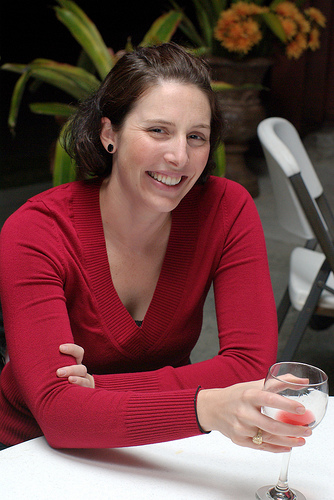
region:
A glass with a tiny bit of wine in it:
[260, 358, 328, 498]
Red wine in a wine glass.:
[277, 405, 315, 427]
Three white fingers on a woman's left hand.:
[49, 341, 94, 388]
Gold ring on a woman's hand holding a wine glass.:
[249, 424, 264, 443]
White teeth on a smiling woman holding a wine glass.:
[147, 170, 182, 186]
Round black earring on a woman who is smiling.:
[106, 142, 115, 152]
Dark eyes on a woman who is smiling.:
[147, 126, 202, 139]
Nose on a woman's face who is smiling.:
[163, 128, 190, 168]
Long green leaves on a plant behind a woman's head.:
[5, 0, 231, 181]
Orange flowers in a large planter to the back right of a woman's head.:
[212, 0, 326, 62]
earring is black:
[101, 142, 121, 153]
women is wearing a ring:
[250, 428, 267, 444]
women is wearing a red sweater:
[3, 227, 107, 341]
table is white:
[83, 460, 172, 496]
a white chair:
[257, 128, 330, 231]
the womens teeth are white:
[152, 173, 180, 186]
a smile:
[141, 164, 192, 195]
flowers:
[222, 13, 265, 50]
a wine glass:
[268, 366, 329, 398]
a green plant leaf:
[53, 14, 113, 61]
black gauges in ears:
[94, 131, 119, 164]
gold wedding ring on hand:
[239, 415, 290, 467]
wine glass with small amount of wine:
[246, 352, 330, 496]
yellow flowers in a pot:
[214, 3, 269, 75]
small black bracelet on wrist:
[187, 382, 213, 437]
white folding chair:
[240, 84, 332, 333]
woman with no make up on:
[46, 37, 271, 295]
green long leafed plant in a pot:
[28, 25, 83, 121]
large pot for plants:
[199, 50, 269, 212]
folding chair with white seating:
[269, 192, 318, 348]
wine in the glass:
[271, 406, 320, 429]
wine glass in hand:
[235, 387, 327, 495]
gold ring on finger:
[239, 427, 272, 456]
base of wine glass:
[268, 477, 309, 497]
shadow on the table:
[137, 449, 216, 494]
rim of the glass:
[266, 359, 322, 379]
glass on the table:
[257, 353, 329, 494]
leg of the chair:
[263, 309, 318, 366]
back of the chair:
[225, 114, 317, 248]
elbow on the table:
[5, 424, 90, 482]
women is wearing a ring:
[247, 429, 262, 447]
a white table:
[52, 461, 153, 491]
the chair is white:
[280, 186, 331, 276]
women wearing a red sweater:
[13, 231, 89, 334]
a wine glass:
[271, 378, 322, 407]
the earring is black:
[104, 144, 115, 153]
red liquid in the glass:
[274, 408, 308, 425]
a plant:
[38, 14, 113, 65]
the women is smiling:
[146, 167, 190, 192]